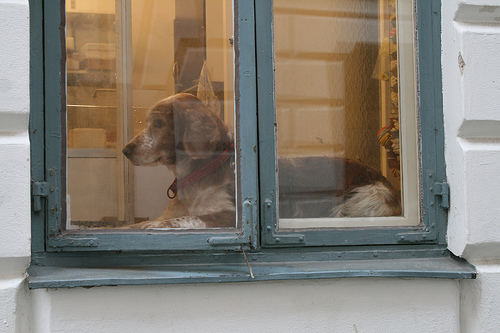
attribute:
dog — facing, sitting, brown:
[126, 98, 398, 231]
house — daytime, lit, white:
[0, 2, 499, 332]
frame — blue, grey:
[30, 0, 446, 264]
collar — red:
[166, 144, 234, 201]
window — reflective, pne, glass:
[65, 1, 235, 227]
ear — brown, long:
[181, 106, 223, 162]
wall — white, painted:
[276, 7, 378, 167]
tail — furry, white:
[326, 183, 396, 220]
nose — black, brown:
[123, 131, 155, 168]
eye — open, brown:
[153, 117, 166, 130]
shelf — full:
[65, 0, 119, 158]